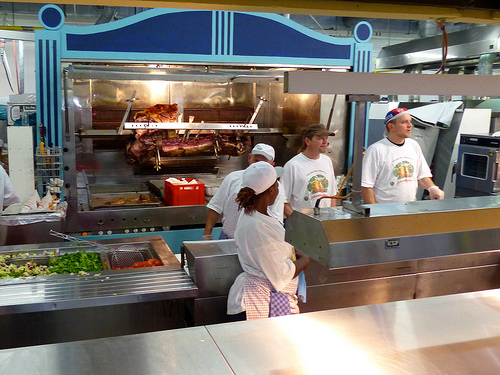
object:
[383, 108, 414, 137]
head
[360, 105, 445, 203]
man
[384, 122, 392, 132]
ear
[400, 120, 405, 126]
eyes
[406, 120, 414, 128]
nose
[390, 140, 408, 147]
neck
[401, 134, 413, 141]
chin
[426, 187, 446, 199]
hand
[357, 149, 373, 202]
arm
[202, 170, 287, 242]
body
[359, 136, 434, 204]
shirt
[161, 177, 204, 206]
crate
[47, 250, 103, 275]
lettuce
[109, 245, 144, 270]
pan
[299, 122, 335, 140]
cap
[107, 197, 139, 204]
meat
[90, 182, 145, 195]
grill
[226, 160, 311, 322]
woman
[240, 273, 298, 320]
apron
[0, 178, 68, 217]
garbage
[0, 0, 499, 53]
ceiling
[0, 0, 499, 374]
kitchen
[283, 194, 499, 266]
counter top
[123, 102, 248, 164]
food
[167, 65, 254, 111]
compartment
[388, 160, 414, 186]
design